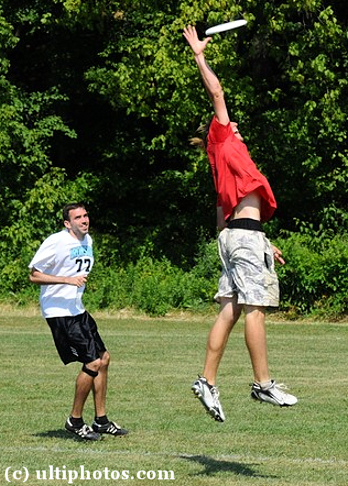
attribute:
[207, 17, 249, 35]
frisbee — mid air, white, flying mid air, flying, round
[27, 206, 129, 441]
man — smiling, looking up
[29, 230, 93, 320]
t shirt — white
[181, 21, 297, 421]
man — jumping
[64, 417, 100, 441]
sneaker — black, white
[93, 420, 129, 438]
sneaker — black, white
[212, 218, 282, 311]
shorts — khaki, white, gray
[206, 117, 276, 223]
t shirt — red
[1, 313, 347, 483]
field — grass, green, yellow green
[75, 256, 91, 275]
number — black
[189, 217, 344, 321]
bush — green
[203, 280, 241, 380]
leg — bare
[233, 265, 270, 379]
leg — bare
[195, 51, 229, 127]
arm — strecthed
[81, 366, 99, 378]
band — black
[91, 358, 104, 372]
knee — bent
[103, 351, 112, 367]
knee — bent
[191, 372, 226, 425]
shoe — white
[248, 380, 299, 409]
shoe — white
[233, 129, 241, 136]
mouth — open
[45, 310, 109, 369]
shorts — black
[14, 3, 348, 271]
trees — green